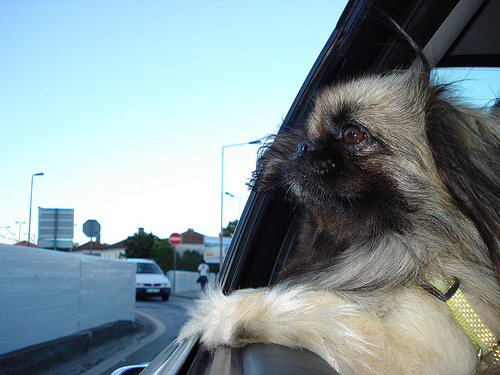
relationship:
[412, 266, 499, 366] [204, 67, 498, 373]
strap on dog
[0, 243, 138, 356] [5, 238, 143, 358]
wall on building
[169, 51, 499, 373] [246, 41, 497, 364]
dog in window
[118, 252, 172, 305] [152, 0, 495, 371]
van behind car